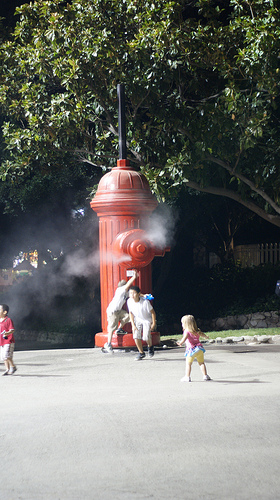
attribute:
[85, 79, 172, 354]
fire hydrant — large, red, enormous, oversized, fake, giant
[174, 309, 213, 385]
kid — playing, young, little, blonde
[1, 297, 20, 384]
kid — playing, small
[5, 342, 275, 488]
road — concrete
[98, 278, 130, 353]
kid — playing, young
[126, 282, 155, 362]
kid — playing, running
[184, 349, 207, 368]
shorts — yellow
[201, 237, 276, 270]
fence — white, wooden, wood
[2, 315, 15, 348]
shirt — red, pink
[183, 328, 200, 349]
shirt — pink, blue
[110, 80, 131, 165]
pole — black, large, metal, tall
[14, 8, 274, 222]
tree — large, green, huge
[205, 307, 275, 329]
border — stone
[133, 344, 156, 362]
sneakers — black